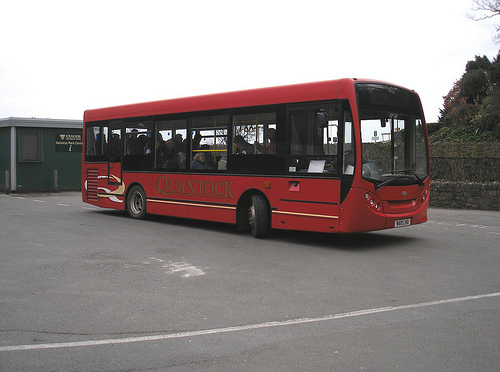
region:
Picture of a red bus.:
[22, 32, 489, 345]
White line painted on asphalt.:
[10, 302, 478, 358]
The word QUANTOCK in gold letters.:
[148, 168, 241, 203]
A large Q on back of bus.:
[68, 168, 131, 210]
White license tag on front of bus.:
[391, 213, 413, 230]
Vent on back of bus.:
[82, 165, 108, 206]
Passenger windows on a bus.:
[86, 107, 352, 177]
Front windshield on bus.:
[351, 77, 428, 194]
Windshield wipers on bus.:
[370, 163, 429, 194]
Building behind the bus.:
[6, 107, 94, 202]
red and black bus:
[52, 94, 430, 238]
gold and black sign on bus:
[150, 177, 235, 202]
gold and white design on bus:
[92, 167, 125, 206]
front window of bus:
[347, 75, 434, 192]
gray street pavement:
[18, 212, 132, 324]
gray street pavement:
[120, 234, 449, 337]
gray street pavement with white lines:
[30, 316, 292, 358]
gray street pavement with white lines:
[397, 240, 483, 355]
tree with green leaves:
[445, 72, 495, 170]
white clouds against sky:
[23, 7, 434, 67]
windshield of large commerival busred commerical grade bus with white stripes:
[92, 92, 463, 302]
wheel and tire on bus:
[232, 180, 295, 248]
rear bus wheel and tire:
[122, 175, 149, 220]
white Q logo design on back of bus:
[79, 162, 139, 215]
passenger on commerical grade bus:
[186, 143, 221, 185]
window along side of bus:
[86, 112, 331, 181]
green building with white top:
[13, 117, 100, 222]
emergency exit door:
[105, 111, 130, 188]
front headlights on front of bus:
[355, 185, 395, 221]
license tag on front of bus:
[385, 202, 425, 234]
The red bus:
[73, 77, 439, 250]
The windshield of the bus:
[356, 81, 431, 186]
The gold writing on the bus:
[153, 173, 235, 203]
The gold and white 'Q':
[82, 170, 127, 208]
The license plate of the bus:
[390, 215, 414, 228]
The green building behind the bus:
[0, 116, 85, 195]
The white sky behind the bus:
[0, 1, 497, 142]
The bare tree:
[462, 1, 499, 48]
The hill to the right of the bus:
[398, 44, 498, 139]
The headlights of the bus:
[363, 183, 430, 210]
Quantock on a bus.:
[137, 160, 241, 207]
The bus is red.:
[83, 75, 428, 232]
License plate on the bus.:
[376, 207, 425, 234]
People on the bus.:
[101, 125, 272, 172]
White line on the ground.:
[96, 298, 451, 338]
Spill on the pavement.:
[118, 239, 218, 294]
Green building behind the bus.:
[1, 120, 92, 195]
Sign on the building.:
[53, 129, 87, 153]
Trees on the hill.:
[438, 51, 498, 141]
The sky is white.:
[59, 22, 272, 77]